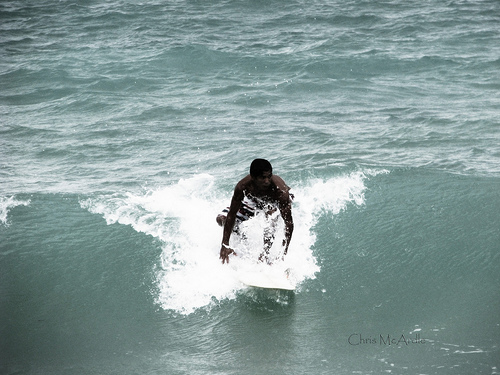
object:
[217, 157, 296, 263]
man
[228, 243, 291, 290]
surfboard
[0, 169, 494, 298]
wave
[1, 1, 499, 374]
ocean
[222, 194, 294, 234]
trunks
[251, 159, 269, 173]
hair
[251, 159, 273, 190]
head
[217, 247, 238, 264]
hand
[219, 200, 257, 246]
leg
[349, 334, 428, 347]
name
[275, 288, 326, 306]
bubbles